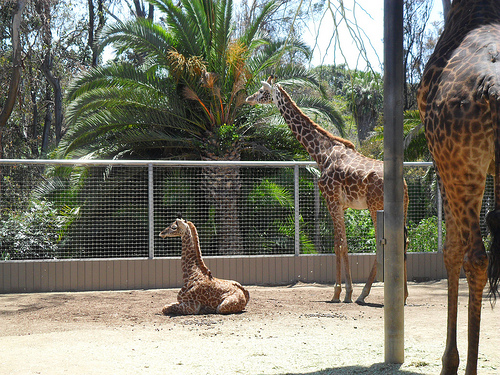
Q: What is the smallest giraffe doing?
A: Sitting down.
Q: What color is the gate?
A: White.